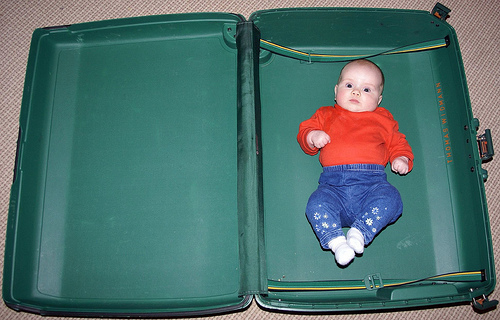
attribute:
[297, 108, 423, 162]
top — red, orange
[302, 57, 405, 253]
baby — looking, awake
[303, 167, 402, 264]
jeans — blue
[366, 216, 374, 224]
flower — small, white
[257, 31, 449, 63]
strap — green, yellow, black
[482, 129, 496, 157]
handle — green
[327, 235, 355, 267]
sock — white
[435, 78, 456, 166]
writing — orange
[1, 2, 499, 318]
capeting — beige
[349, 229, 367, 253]
sock — white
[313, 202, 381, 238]
pattern — white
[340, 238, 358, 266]
socks — white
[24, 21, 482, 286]
suitcase — green, opened, open